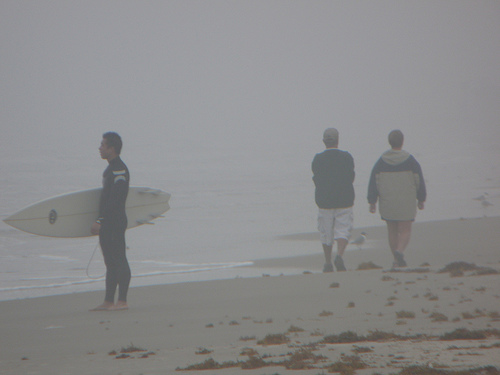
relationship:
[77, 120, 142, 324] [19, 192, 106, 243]
surfer holding board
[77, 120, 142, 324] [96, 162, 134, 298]
surfer wearing wetsuit